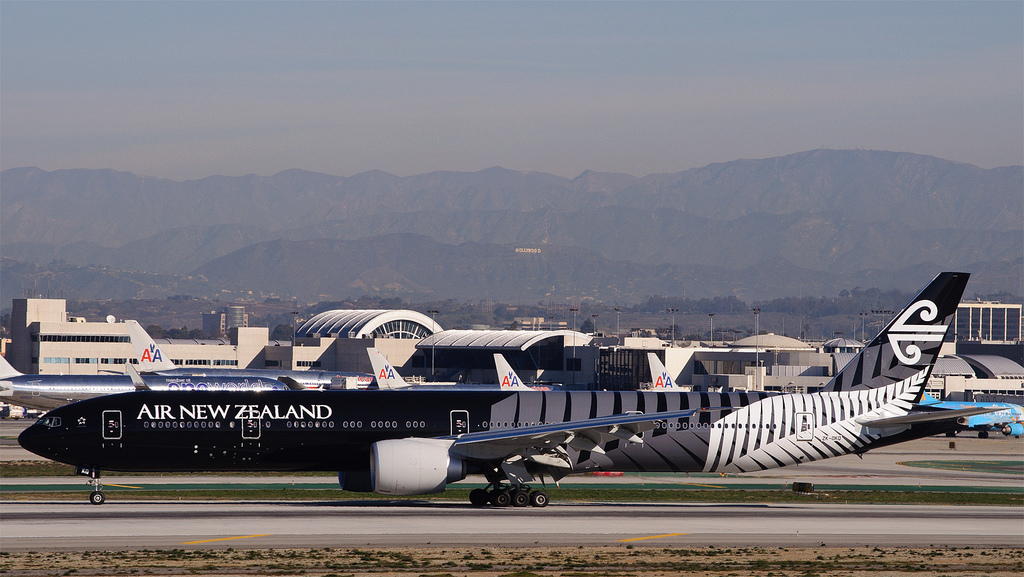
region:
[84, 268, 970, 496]
The plan has black and white stripes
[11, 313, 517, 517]
The black plane has white letters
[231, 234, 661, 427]
The building has a glass arch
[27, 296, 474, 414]
The Plane is silver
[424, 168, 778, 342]
A sign is on the mountain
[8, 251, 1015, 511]
Plane is on the ground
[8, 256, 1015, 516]
Airplane on the ground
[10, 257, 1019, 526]
Airplane is on the ground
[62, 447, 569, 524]
Landing gear deployed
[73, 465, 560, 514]
Landing gear is deployed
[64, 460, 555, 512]
Landing gears deployed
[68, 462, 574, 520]
Landing gears are deployed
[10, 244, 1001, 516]
Black and white plane on the ground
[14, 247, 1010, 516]
Black and white airplane is on the ground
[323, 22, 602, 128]
white and grey sky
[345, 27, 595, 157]
white clouds in sky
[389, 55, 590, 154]
layered clouds in sky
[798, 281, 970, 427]
black and white tail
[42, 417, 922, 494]
black and white plane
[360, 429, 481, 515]
plane has white engines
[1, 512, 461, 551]
runway is light grey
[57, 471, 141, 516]
small and black wheels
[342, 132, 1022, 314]
tall mountain in distance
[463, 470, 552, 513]
landing gear on airplane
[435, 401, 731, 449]
wing of air plane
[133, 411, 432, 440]
windows on an airplane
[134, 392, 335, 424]
logo on side of airplane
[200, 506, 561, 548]
runway for an airplane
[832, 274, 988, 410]
tail of an airplane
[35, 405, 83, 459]
cockpit of an airplane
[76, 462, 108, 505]
front wheels of landing gear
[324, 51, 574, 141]
hazy sky over mountains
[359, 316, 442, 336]
windows on front of building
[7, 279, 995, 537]
black and white plane on ground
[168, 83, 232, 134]
white clouds in blue sky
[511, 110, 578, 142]
white clouds in blue sky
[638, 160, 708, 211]
white clouds in blue sky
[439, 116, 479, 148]
white clouds in blue sky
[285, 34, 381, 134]
white clouds in blue sky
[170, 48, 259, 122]
white clouds in blue sky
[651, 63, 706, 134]
white clouds in blue sky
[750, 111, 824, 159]
white clouds in blue sky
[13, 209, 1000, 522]
a large black and white plane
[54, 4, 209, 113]
Large body of skies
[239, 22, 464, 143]
Large body of skies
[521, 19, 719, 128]
Large body of skies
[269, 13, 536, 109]
Large body of skies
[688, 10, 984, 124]
Large body of skies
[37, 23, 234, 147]
Large body of skies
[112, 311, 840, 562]
airplanes at an airport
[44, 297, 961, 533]
The plane is on the runway.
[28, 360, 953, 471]
The plane is blue and gray.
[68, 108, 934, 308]
Mountains behind the airport in view.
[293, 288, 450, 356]
The roof of the building.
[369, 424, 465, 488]
The engine of the plane.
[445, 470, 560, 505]
The landing gear of the plane.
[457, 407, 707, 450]
Wing of the plane.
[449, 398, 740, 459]
Wing of the plane.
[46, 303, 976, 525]
an plane that is black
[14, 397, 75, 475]
the nose of a plane